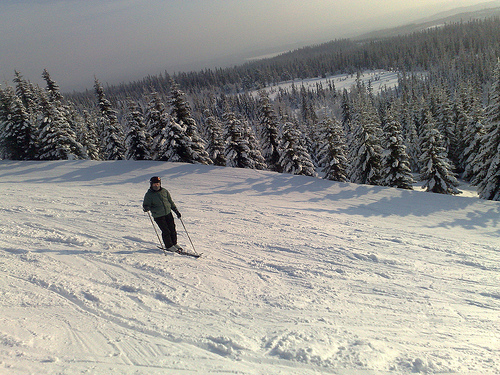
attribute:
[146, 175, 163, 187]
helmet — red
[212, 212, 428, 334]
tracks — ski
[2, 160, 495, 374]
snow — powder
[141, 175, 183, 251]
skier — athletic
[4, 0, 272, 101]
skies — cloudy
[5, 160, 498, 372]
field — cleared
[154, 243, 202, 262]
snow skis — pair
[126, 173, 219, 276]
man — skiing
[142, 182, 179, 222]
coat — green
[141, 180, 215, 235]
jacket — dark green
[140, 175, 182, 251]
man — leaning, skiing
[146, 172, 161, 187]
hat — his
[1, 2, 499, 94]
sky — grey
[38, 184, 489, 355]
ski slope — white, snow-covered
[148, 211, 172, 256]
stick — another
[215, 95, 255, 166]
tree — snow-covered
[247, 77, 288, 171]
tree — snow-covered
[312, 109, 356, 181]
tree — snow-covered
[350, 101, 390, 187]
tree — snow-covered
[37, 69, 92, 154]
tree — snow-covered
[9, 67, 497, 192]
trees — green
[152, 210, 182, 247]
pants — black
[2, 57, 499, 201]
trees — snow-covered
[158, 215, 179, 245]
pants — black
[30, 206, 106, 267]
tracks — ski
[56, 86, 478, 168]
trees — several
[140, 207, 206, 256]
poles — ski